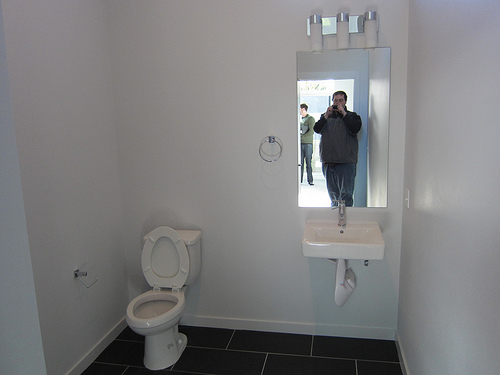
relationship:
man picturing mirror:
[315, 89, 356, 207] [290, 43, 393, 210]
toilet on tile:
[125, 224, 205, 374] [66, 315, 409, 373]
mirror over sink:
[290, 43, 393, 210] [302, 220, 387, 273]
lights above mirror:
[295, 9, 390, 47] [290, 43, 393, 210]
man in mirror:
[315, 89, 356, 207] [290, 43, 393, 210]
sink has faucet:
[302, 220, 387, 273] [338, 200, 347, 225]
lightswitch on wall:
[402, 188, 413, 211] [396, 1, 499, 374]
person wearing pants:
[313, 89, 365, 209] [322, 162, 355, 207]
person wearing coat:
[313, 89, 365, 209] [317, 107, 360, 167]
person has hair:
[313, 89, 365, 209] [333, 88, 349, 104]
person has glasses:
[313, 89, 365, 209] [334, 97, 343, 102]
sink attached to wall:
[302, 220, 387, 273] [396, 1, 499, 374]